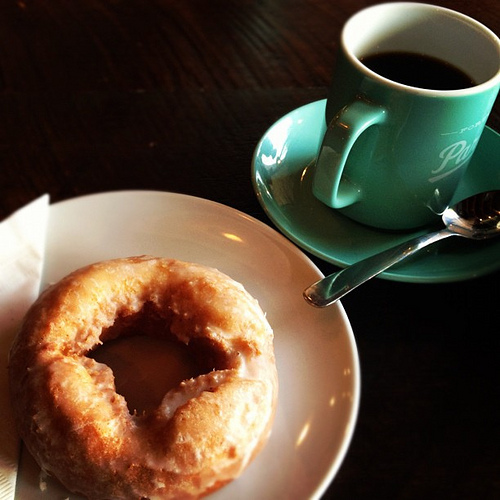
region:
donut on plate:
[3, 244, 283, 495]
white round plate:
[13, 175, 367, 497]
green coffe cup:
[308, 3, 498, 233]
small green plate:
[244, 80, 496, 296]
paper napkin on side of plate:
[0, 182, 55, 498]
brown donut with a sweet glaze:
[9, 231, 291, 498]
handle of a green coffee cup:
[306, 97, 392, 218]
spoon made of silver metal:
[301, 185, 498, 316]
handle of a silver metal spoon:
[297, 223, 451, 309]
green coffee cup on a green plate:
[239, 21, 497, 290]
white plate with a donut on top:
[0, 180, 365, 497]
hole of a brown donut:
[87, 321, 199, 420]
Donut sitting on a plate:
[10, 256, 272, 498]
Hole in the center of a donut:
[92, 314, 216, 414]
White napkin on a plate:
[0, 193, 52, 493]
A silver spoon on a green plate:
[307, 187, 497, 307]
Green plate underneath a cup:
[252, 98, 498, 287]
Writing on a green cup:
[431, 118, 476, 184]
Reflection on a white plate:
[292, 414, 315, 446]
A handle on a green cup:
[308, 103, 382, 204]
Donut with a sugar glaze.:
[12, 255, 284, 499]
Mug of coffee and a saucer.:
[254, 3, 499, 287]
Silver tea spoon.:
[302, 187, 497, 309]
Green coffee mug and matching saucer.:
[247, 1, 497, 288]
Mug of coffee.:
[311, 1, 498, 233]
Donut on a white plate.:
[1, 184, 366, 499]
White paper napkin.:
[0, 192, 51, 499]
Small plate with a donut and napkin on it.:
[2, 188, 362, 498]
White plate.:
[1, 188, 365, 499]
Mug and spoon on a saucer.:
[252, 1, 497, 308]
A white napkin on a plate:
[4, 191, 44, 498]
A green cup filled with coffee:
[312, 3, 498, 221]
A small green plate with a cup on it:
[225, 96, 499, 283]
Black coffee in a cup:
[358, 48, 476, 99]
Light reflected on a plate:
[290, 415, 321, 454]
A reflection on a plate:
[257, 125, 304, 216]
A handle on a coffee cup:
[314, 98, 377, 209]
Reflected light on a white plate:
[220, 229, 252, 243]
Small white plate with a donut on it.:
[0, 184, 362, 499]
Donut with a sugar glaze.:
[10, 252, 280, 499]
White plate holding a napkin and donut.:
[2, 188, 360, 498]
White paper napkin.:
[0, 191, 55, 498]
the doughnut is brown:
[22, 249, 279, 488]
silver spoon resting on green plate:
[301, 177, 498, 317]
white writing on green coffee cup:
[422, 120, 482, 187]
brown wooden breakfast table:
[8, 4, 250, 172]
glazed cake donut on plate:
[11, 244, 284, 496]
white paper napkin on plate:
[4, 192, 48, 496]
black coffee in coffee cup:
[351, 40, 497, 128]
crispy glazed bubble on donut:
[139, 360, 274, 497]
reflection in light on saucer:
[250, 106, 294, 173]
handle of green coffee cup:
[299, 89, 373, 220]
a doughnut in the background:
[17, 235, 322, 493]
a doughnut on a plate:
[18, 194, 341, 494]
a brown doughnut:
[37, 211, 352, 481]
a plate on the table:
[24, 161, 416, 491]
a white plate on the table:
[33, 130, 389, 497]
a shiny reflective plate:
[29, 135, 434, 498]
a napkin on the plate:
[3, 141, 73, 498]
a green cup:
[333, 5, 497, 261]